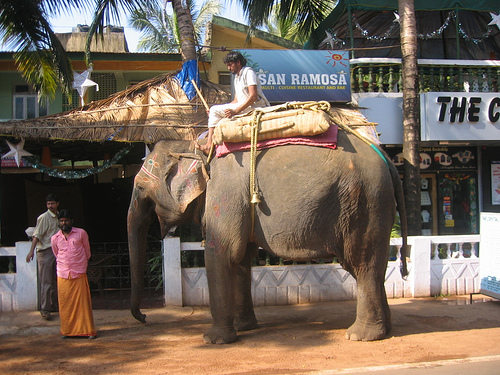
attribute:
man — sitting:
[194, 49, 270, 153]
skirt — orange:
[54, 270, 98, 338]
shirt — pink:
[51, 227, 91, 280]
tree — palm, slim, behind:
[393, 2, 425, 239]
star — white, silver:
[3, 138, 36, 170]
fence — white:
[163, 234, 495, 304]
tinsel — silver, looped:
[345, 11, 399, 43]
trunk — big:
[124, 211, 153, 325]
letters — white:
[433, 94, 500, 126]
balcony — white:
[349, 57, 498, 120]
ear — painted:
[164, 150, 210, 213]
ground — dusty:
[0, 298, 499, 375]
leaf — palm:
[1, 2, 74, 95]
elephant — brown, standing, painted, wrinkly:
[127, 128, 409, 341]